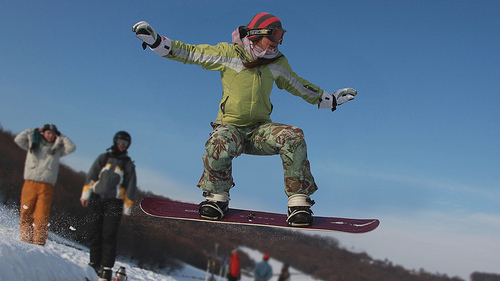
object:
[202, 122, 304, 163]
knees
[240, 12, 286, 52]
helmet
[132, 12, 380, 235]
person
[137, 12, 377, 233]
person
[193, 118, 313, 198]
pants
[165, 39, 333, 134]
jacket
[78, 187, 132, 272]
pants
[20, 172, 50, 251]
pants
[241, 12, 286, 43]
marvin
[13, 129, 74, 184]
jacket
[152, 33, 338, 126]
snowboarding jacket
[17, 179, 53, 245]
snowboarding pants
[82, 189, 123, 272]
snowboarding pants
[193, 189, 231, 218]
snowboarding boots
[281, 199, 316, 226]
snowboarding boots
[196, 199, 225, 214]
bindings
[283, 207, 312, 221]
bindings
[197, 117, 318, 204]
snowboarding pants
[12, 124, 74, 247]
observer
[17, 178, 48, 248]
pants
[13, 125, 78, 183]
jacket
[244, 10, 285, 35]
beanie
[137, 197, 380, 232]
snowboard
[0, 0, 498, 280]
sky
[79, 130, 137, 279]
person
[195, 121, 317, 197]
pants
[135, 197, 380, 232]
board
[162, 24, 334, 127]
jacket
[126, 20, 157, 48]
glove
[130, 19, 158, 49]
hand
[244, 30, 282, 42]
goggles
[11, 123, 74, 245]
person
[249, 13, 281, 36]
hat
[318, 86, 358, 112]
left glove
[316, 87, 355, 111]
hands